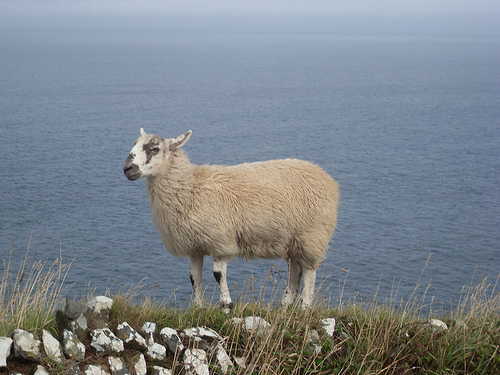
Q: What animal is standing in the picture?
A: A goat.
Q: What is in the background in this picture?
A: Water.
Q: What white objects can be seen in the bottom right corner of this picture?
A: Rocks.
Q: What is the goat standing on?
A: A hill.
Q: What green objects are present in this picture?
A: Grass.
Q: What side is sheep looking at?
A: Left.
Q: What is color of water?
A: Blue.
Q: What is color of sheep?
A: White, tan.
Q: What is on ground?
A: Rocks.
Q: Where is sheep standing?
A: Behind rocks.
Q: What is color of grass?
A: Green.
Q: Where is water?
A: Background of sheep.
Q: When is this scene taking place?
A: Daytime.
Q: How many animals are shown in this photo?
A: One.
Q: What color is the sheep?
A: White.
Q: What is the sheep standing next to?
A: Body of water.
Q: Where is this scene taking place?
A: Beside water.